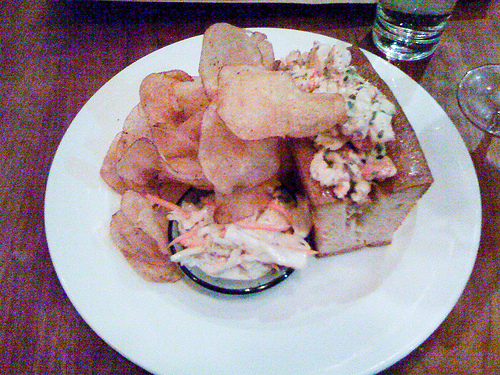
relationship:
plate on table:
[39, 14, 490, 375] [4, 2, 495, 372]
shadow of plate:
[484, 158, 499, 336] [39, 14, 490, 375]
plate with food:
[39, 14, 490, 375] [92, 14, 445, 303]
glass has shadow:
[369, 1, 461, 62] [404, 58, 429, 78]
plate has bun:
[39, 14, 490, 375] [280, 42, 435, 259]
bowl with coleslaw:
[164, 174, 310, 297] [175, 196, 299, 276]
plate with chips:
[39, 14, 490, 375] [87, 16, 337, 224]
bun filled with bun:
[275, 33, 438, 263] [280, 42, 435, 259]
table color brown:
[4, 2, 495, 372] [4, 6, 101, 81]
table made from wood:
[4, 2, 495, 372] [4, 6, 101, 81]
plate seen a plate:
[39, 14, 490, 375] [39, 14, 490, 375]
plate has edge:
[39, 14, 490, 375] [36, 109, 70, 315]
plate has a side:
[39, 14, 490, 375] [87, 16, 337, 224]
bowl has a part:
[164, 174, 310, 297] [175, 196, 299, 276]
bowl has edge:
[164, 174, 310, 297] [202, 280, 287, 300]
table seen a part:
[4, 2, 495, 372] [4, 6, 101, 81]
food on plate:
[92, 14, 445, 303] [39, 14, 490, 375]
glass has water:
[369, 1, 461, 62] [378, 5, 451, 44]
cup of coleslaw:
[164, 174, 310, 297] [175, 196, 299, 276]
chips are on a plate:
[87, 16, 337, 224] [39, 14, 490, 375]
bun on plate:
[280, 42, 435, 259] [39, 14, 490, 375]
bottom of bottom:
[456, 64, 498, 140] [456, 64, 498, 140]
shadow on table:
[463, 149, 498, 342] [4, 2, 495, 372]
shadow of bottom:
[463, 149, 498, 342] [456, 64, 498, 140]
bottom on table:
[456, 64, 498, 140] [4, 2, 495, 372]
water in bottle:
[372, 3, 447, 58] [369, 1, 461, 62]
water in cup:
[369, 1, 461, 62] [369, 1, 461, 62]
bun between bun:
[280, 42, 435, 259] [280, 42, 435, 259]